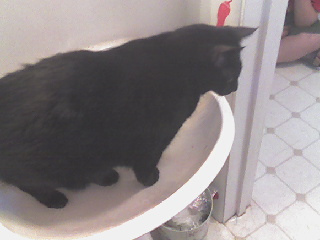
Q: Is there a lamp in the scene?
A: No, there are no lamps.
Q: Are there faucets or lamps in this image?
A: No, there are no lamps or faucets.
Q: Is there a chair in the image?
A: Yes, there is a chair.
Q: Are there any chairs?
A: Yes, there is a chair.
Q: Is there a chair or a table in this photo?
A: Yes, there is a chair.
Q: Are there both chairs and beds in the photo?
A: No, there is a chair but no beds.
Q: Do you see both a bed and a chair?
A: No, there is a chair but no beds.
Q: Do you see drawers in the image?
A: No, there are no drawers.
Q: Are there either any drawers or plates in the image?
A: No, there are no drawers or plates.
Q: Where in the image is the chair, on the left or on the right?
A: The chair is on the right of the image.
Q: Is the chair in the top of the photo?
A: Yes, the chair is in the top of the image.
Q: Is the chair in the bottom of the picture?
A: No, the chair is in the top of the image.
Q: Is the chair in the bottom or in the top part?
A: The chair is in the top of the image.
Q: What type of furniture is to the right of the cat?
A: The piece of furniture is a chair.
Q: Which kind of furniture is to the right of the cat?
A: The piece of furniture is a chair.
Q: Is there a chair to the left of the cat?
A: No, the chair is to the right of the cat.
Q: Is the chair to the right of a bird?
A: No, the chair is to the right of the cat.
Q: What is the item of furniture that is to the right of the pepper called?
A: The piece of furniture is a chair.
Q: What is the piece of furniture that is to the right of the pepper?
A: The piece of furniture is a chair.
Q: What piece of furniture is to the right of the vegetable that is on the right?
A: The piece of furniture is a chair.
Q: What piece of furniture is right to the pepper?
A: The piece of furniture is a chair.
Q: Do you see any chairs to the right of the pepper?
A: Yes, there is a chair to the right of the pepper.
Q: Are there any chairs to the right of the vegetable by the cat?
A: Yes, there is a chair to the right of the pepper.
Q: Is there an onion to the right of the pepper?
A: No, there is a chair to the right of the pepper.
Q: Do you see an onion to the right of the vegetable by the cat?
A: No, there is a chair to the right of the pepper.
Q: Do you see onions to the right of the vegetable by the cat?
A: No, there is a chair to the right of the pepper.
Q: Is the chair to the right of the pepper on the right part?
A: Yes, the chair is to the right of the pepper.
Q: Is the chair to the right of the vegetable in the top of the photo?
A: Yes, the chair is to the right of the pepper.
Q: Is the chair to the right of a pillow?
A: No, the chair is to the right of the pepper.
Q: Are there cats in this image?
A: Yes, there is a cat.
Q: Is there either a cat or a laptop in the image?
A: Yes, there is a cat.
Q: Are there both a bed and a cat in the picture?
A: No, there is a cat but no beds.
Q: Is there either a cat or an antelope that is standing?
A: Yes, the cat is standing.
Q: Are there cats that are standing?
A: Yes, there is a cat that is standing.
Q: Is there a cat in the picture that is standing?
A: Yes, there is a cat that is standing.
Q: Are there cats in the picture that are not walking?
A: Yes, there is a cat that is standing.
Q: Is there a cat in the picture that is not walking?
A: Yes, there is a cat that is standing.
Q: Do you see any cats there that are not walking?
A: Yes, there is a cat that is standing .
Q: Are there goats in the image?
A: No, there are no goats.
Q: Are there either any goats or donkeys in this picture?
A: No, there are no goats or donkeys.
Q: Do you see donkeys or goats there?
A: No, there are no goats or donkeys.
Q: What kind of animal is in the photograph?
A: The animal is a cat.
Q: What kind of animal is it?
A: The animal is a cat.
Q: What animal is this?
A: That is a cat.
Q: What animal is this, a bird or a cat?
A: That is a cat.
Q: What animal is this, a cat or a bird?
A: That is a cat.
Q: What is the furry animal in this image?
A: The animal is a cat.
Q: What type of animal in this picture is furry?
A: The animal is a cat.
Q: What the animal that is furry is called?
A: The animal is a cat.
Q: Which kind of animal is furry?
A: The animal is a cat.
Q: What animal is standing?
A: The animal is a cat.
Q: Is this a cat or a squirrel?
A: This is a cat.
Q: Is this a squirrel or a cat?
A: This is a cat.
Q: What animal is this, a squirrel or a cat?
A: This is a cat.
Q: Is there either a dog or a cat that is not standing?
A: No, there is a cat but it is standing.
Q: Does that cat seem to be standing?
A: Yes, the cat is standing.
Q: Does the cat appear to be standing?
A: Yes, the cat is standing.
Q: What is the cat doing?
A: The cat is standing.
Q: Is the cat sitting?
A: No, the cat is standing.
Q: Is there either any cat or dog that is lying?
A: No, there is a cat but it is standing.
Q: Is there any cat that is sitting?
A: No, there is a cat but it is standing.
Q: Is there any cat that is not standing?
A: No, there is a cat but it is standing.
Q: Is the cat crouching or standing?
A: The cat is standing.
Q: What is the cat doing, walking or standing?
A: The cat is standing.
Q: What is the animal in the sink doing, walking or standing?
A: The cat is standing.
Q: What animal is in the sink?
A: The animal is a cat.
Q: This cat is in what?
A: The cat is in the sink.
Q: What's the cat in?
A: The cat is in the sink.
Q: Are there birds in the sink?
A: No, there is a cat in the sink.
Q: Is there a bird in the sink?
A: No, there is a cat in the sink.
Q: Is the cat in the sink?
A: Yes, the cat is in the sink.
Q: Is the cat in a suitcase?
A: No, the cat is in the sink.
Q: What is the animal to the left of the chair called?
A: The animal is a cat.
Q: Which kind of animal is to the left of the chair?
A: The animal is a cat.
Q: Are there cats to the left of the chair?
A: Yes, there is a cat to the left of the chair.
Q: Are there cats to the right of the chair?
A: No, the cat is to the left of the chair.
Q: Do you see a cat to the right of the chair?
A: No, the cat is to the left of the chair.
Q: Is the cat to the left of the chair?
A: Yes, the cat is to the left of the chair.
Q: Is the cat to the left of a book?
A: No, the cat is to the left of the chair.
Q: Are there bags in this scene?
A: Yes, there is a bag.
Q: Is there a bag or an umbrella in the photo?
A: Yes, there is a bag.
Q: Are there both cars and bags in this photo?
A: No, there is a bag but no cars.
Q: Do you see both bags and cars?
A: No, there is a bag but no cars.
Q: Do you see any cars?
A: No, there are no cars.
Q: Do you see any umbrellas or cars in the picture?
A: No, there are no cars or umbrellas.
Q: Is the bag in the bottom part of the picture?
A: Yes, the bag is in the bottom of the image.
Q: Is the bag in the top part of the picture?
A: No, the bag is in the bottom of the image.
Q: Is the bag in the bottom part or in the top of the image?
A: The bag is in the bottom of the image.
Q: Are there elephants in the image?
A: No, there are no elephants.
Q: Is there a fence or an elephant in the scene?
A: No, there are no elephants or fences.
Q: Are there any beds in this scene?
A: No, there are no beds.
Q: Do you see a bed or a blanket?
A: No, there are no beds or blankets.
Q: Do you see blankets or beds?
A: No, there are no beds or blankets.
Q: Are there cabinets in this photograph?
A: No, there are no cabinets.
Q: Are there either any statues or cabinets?
A: No, there are no cabinets or statues.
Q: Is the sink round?
A: Yes, the sink is round.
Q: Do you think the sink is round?
A: Yes, the sink is round.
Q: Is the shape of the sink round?
A: Yes, the sink is round.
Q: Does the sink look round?
A: Yes, the sink is round.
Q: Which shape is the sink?
A: The sink is round.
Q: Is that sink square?
A: No, the sink is round.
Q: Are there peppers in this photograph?
A: Yes, there is a pepper.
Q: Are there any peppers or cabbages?
A: Yes, there is a pepper.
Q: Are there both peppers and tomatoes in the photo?
A: No, there is a pepper but no tomatoes.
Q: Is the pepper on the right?
A: Yes, the pepper is on the right of the image.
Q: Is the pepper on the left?
A: No, the pepper is on the right of the image.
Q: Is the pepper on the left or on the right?
A: The pepper is on the right of the image.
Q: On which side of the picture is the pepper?
A: The pepper is on the right of the image.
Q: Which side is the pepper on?
A: The pepper is on the right of the image.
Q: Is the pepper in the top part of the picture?
A: Yes, the pepper is in the top of the image.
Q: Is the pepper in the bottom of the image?
A: No, the pepper is in the top of the image.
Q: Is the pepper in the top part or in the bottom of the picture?
A: The pepper is in the top of the image.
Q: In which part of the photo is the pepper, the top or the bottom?
A: The pepper is in the top of the image.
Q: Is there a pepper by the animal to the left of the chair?
A: Yes, there is a pepper by the cat.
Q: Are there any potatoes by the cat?
A: No, there is a pepper by the cat.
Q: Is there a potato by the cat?
A: No, there is a pepper by the cat.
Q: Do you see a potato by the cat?
A: No, there is a pepper by the cat.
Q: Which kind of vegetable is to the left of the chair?
A: The vegetable is a pepper.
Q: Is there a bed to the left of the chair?
A: No, there is a pepper to the left of the chair.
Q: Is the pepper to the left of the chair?
A: Yes, the pepper is to the left of the chair.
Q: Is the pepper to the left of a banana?
A: No, the pepper is to the left of the chair.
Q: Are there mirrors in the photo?
A: No, there are no mirrors.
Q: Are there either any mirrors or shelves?
A: No, there are no mirrors or shelves.